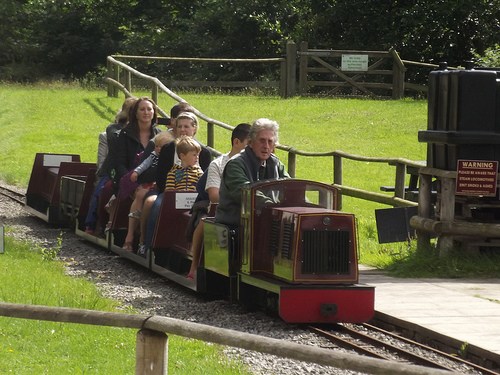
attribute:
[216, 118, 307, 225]
man — a train conductor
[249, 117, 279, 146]
hair — gray, short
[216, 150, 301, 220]
jacket — green, gray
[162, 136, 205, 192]
boy — little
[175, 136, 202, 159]
hair — brown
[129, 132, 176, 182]
boy — little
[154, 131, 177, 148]
hair — blond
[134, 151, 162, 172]
shirt — striped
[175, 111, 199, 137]
hair — short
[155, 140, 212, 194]
jacket — black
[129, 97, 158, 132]
hair — long, dark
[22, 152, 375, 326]
train — child's train, small, miniature, children's train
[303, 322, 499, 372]
train tracks — small, triple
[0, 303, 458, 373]
rail — wooden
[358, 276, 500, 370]
platform — wooden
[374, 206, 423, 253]
sign — warning sign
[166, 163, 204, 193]
sweater — striped, yellow, brown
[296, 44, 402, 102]
gate — wooden, brown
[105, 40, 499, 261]
fence — wooden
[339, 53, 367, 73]
sign — white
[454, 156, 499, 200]
sign — red, white, warning sign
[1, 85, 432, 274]
area — grassy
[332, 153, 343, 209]
fence post — wooden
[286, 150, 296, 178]
fence post — wooden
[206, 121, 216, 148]
fence post — wooden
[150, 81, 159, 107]
fence post — wooden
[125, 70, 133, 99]
fence post — wooden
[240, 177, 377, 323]
train engine — red